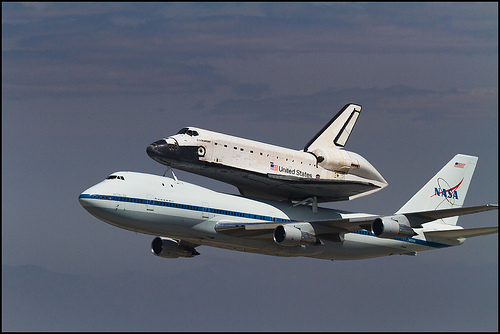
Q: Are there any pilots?
A: No, there are no pilots.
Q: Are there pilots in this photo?
A: No, there are no pilots.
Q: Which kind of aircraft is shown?
A: The aircraft is a jet.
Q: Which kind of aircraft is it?
A: The aircraft is a jet.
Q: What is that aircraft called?
A: This is a jet.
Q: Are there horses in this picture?
A: No, there are no horses.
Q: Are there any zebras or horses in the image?
A: No, there are no horses or zebras.